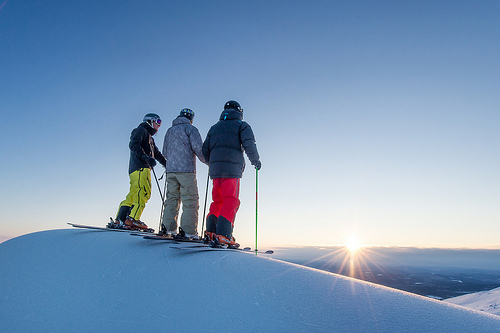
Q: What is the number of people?
A: 3.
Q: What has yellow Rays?
A: Sun.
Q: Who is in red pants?
A: Person on right.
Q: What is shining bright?
A: The sun.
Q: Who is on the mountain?
A: Skiers.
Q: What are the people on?
A: Snow.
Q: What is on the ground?
A: Snow.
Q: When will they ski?
A: Soon.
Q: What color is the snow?
A: White.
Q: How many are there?
A: 3.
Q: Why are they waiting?
A: To leave.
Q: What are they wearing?
A: Jackets.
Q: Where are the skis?
A: In the snow.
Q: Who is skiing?
A: The guys.